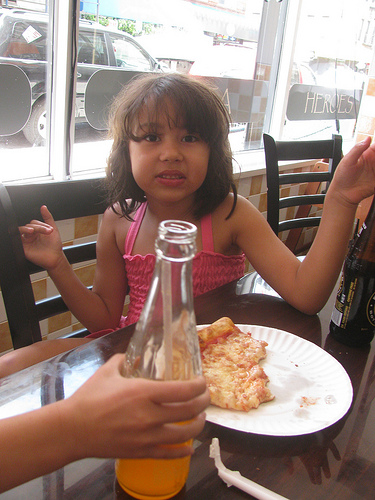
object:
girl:
[0, 72, 374, 377]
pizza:
[156, 314, 275, 412]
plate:
[171, 324, 354, 437]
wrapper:
[207, 436, 289, 499]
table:
[0, 240, 374, 499]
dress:
[82, 189, 249, 348]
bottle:
[112, 218, 205, 499]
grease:
[291, 404, 309, 420]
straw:
[159, 259, 175, 381]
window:
[274, 1, 374, 150]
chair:
[263, 134, 344, 256]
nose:
[157, 130, 184, 165]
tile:
[74, 215, 101, 243]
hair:
[97, 71, 241, 226]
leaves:
[124, 24, 134, 34]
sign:
[284, 82, 364, 120]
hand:
[78, 351, 212, 460]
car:
[0, 8, 172, 148]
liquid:
[113, 414, 194, 499]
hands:
[19, 203, 65, 271]